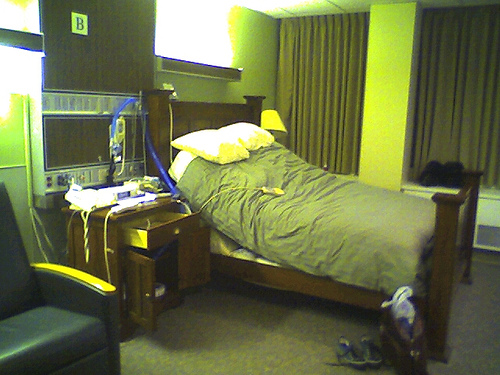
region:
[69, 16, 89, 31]
The letter B on the wall.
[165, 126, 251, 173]
The left pillow on the bed.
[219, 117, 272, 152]
The right pillow on the bed.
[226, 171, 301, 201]
The remote on the bed.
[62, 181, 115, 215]
The phone on the desk.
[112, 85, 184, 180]
The blue breathing tube on the wall.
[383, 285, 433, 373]
The brown bag on the floor.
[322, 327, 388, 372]
The sneakers next to the brown bag.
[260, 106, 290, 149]
The lamp on the right to the bed.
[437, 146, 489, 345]
The wooden footboard of the bed.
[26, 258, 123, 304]
arm on the chair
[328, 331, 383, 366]
shoes on the floor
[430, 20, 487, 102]
a curtain on window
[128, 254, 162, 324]
door on the nighstand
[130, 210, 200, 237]
open drawer on nighstand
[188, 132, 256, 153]
pillow on the bed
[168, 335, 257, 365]
carpet on the floor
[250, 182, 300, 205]
remote unit for bed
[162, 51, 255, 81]
light above the bed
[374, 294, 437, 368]
brown bag on floot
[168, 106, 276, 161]
two pillows on bed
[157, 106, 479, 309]
hospital bed with sheets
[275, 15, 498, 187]
windows with long blinds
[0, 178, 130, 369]
black reclining chair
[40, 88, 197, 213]
medical monitoring equipment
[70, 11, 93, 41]
label with the letter B on it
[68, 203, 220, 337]
dresser with doors and drawers open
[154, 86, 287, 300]
headboard of hospital bed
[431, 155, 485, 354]
footboard of hospital bed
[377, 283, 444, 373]
bag sitting beside hospital bed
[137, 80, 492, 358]
brown wood hospital bed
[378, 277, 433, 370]
brown leather hand bag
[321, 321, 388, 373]
blue tie casual shoes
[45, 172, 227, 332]
large wood night stand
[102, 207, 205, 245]
open top drawer on nightstand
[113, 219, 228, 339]
open cabinet doors on night stand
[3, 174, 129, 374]
blue leather easy chair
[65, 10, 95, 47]
letter B in white square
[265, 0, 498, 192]
green pleated window curtains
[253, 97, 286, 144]
small white lamp shade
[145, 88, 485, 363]
Hospital bed with a wooden frame.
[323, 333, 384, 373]
Black athletic shoes with blue shoelaces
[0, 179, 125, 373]
Blue lounge chair with wooden armrest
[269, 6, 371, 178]
Brown curtain pulled across the window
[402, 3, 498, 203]
Brown curtain pulled across the window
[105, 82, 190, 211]
Medical devices and tubing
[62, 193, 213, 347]
Wooden cabinet with doors and drawer open.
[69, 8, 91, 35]
Sign that says "B"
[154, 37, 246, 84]
Light above the bed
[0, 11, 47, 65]
Light above the chair.